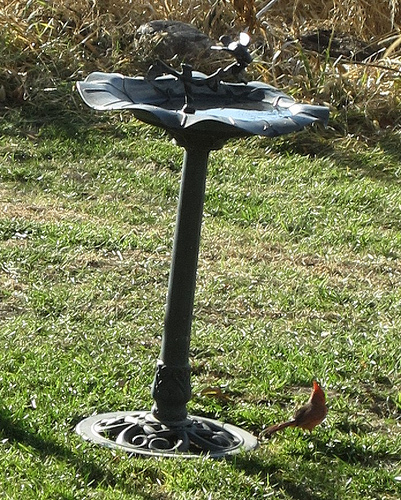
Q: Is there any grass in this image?
A: Yes, there is grass.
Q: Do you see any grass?
A: Yes, there is grass.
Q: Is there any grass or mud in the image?
A: Yes, there is grass.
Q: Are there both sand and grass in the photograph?
A: No, there is grass but no sand.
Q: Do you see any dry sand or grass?
A: Yes, there is dry grass.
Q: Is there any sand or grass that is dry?
A: Yes, the grass is dry.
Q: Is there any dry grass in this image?
A: Yes, there is dry grass.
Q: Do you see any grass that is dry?
A: Yes, there is dry grass.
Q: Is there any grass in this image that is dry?
A: Yes, there is grass that is dry.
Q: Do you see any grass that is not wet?
A: Yes, there is dry grass.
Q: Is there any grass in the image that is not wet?
A: Yes, there is dry grass.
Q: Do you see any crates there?
A: No, there are no crates.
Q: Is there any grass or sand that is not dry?
A: No, there is grass but it is dry.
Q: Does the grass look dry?
A: Yes, the grass is dry.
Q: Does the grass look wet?
A: No, the grass is dry.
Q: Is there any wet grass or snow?
A: No, there is grass but it is dry.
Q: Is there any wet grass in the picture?
A: No, there is grass but it is dry.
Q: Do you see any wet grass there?
A: No, there is grass but it is dry.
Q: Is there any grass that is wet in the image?
A: No, there is grass but it is dry.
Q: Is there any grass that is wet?
A: No, there is grass but it is dry.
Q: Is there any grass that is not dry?
A: No, there is grass but it is dry.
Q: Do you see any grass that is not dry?
A: No, there is grass but it is dry.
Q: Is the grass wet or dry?
A: The grass is dry.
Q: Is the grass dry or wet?
A: The grass is dry.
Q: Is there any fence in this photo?
A: No, there are no fences.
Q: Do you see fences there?
A: No, there are no fences.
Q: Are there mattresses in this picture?
A: No, there are no mattresses.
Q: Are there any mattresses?
A: No, there are no mattresses.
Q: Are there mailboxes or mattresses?
A: No, there are no mattresses or mailboxes.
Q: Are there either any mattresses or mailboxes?
A: No, there are no mattresses or mailboxes.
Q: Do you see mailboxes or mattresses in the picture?
A: No, there are no mattresses or mailboxes.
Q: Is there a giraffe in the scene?
A: No, there are no giraffes.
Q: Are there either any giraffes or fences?
A: No, there are no giraffes or fences.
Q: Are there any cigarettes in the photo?
A: No, there are no cigarettes.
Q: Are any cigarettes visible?
A: No, there are no cigarettes.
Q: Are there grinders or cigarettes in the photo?
A: No, there are no cigarettes or grinders.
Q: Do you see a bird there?
A: Yes, there is a bird.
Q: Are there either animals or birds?
A: Yes, there is a bird.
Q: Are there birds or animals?
A: Yes, there is a bird.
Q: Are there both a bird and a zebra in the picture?
A: No, there is a bird but no zebras.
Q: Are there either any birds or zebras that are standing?
A: Yes, the bird is standing.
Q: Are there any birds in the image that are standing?
A: Yes, there is a bird that is standing.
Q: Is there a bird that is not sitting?
A: Yes, there is a bird that is standing.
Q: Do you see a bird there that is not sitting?
A: Yes, there is a bird that is standing .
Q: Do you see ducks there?
A: No, there are no ducks.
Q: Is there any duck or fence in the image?
A: No, there are no ducks or fences.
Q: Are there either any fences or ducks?
A: No, there are no ducks or fences.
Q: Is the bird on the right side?
A: Yes, the bird is on the right of the image.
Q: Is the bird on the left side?
A: No, the bird is on the right of the image.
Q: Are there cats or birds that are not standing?
A: No, there is a bird but it is standing.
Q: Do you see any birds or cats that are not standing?
A: No, there is a bird but it is standing.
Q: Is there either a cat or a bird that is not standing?
A: No, there is a bird but it is standing.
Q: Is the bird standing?
A: Yes, the bird is standing.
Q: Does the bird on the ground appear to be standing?
A: Yes, the bird is standing.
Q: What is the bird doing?
A: The bird is standing.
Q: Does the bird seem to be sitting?
A: No, the bird is standing.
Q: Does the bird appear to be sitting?
A: No, the bird is standing.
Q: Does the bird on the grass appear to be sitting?
A: No, the bird is standing.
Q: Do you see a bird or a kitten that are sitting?
A: No, there is a bird but it is standing.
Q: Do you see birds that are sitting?
A: No, there is a bird but it is standing.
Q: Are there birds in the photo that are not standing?
A: No, there is a bird but it is standing.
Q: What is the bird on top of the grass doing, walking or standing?
A: The bird is standing.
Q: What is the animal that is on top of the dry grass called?
A: The animal is a bird.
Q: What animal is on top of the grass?
A: The animal is a bird.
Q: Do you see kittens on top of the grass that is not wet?
A: No, there is a bird on top of the grass.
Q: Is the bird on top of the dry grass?
A: Yes, the bird is on top of the grass.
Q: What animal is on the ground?
A: The animal is a bird.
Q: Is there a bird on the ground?
A: Yes, there is a bird on the ground.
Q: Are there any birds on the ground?
A: Yes, there is a bird on the ground.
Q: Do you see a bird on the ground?
A: Yes, there is a bird on the ground.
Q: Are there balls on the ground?
A: No, there is a bird on the ground.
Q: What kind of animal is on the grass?
A: The animal is a bird.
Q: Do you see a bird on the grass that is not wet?
A: Yes, there is a bird on the grass.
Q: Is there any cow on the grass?
A: No, there is a bird on the grass.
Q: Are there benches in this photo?
A: No, there are no benches.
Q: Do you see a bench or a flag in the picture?
A: No, there are no benches or flags.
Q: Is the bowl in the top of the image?
A: Yes, the bowl is in the top of the image.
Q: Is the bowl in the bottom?
A: No, the bowl is in the top of the image.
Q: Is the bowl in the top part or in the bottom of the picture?
A: The bowl is in the top of the image.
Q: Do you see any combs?
A: No, there are no combs.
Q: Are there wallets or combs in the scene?
A: No, there are no combs or wallets.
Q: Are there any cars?
A: No, there are no cars.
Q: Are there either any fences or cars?
A: No, there are no cars or fences.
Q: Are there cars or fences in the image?
A: No, there are no cars or fences.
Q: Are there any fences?
A: No, there are no fences.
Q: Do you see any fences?
A: No, there are no fences.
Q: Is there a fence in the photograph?
A: No, there are no fences.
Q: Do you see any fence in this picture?
A: No, there are no fences.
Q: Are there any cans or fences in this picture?
A: No, there are no fences or cans.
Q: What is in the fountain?
A: The water is in the fountain.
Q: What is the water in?
A: The water is in the fountain.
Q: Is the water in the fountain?
A: Yes, the water is in the fountain.